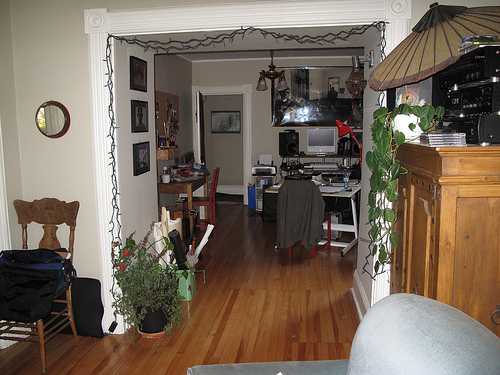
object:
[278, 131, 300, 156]
speaker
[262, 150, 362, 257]
desk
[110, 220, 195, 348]
plant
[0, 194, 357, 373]
floor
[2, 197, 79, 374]
chair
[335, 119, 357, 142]
lamp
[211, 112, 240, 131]
picture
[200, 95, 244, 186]
wall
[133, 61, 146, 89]
picture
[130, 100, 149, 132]
picture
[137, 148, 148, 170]
picture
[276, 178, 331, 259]
chair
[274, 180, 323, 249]
jacket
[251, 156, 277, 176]
printer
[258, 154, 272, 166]
paper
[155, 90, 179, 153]
bulletin board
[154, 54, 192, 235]
wall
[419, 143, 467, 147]
cds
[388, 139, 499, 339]
hutch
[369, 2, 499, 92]
umbrella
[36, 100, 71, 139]
mirror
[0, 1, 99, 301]
wall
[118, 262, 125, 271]
flower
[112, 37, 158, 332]
wall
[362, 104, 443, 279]
plant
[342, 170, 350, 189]
water bottle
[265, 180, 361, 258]
desk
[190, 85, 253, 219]
doorway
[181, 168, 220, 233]
chair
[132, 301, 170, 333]
pot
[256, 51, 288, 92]
light fixture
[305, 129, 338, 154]
monitor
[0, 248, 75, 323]
bag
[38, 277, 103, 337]
bag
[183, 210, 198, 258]
umbrella